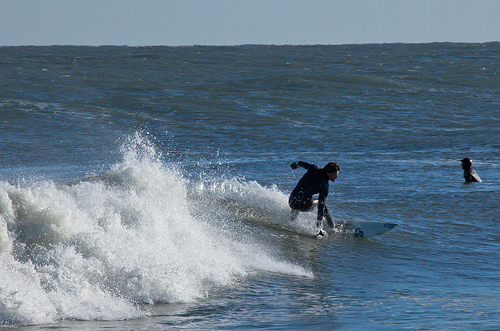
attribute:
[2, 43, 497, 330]
water — blue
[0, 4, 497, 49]
sky — blue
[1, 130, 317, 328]
waves — white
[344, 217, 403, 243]
decals — dark blue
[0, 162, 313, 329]
wave — white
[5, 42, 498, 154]
ocean — calm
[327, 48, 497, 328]
water — calm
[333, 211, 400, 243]
surfboard — blue